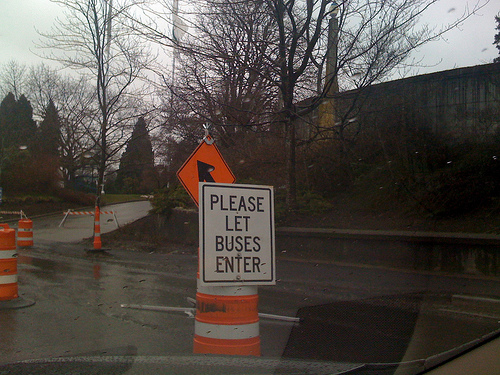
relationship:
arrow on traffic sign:
[191, 156, 219, 186] [167, 116, 277, 280]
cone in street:
[89, 206, 106, 253] [3, 233, 429, 373]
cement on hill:
[49, 199, 111, 244] [205, 111, 450, 226]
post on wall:
[313, 0, 349, 151] [259, 63, 467, 150]